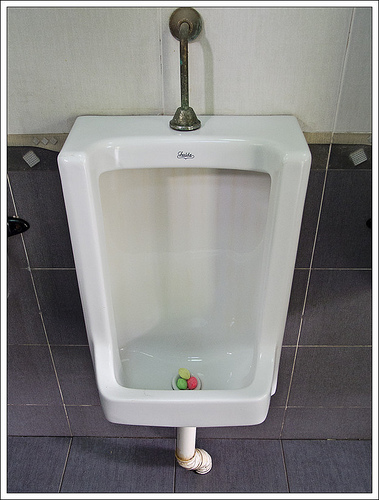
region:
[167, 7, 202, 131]
Rusty metal hardware coming out of the urinal.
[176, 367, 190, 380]
Yellow urinal cake.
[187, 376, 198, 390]
Pink urinal cake.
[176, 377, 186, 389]
A green urinal cake.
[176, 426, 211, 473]
A white pipe going into the floor.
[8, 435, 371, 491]
Four grey floor tile.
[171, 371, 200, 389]
White round drain under the urinal cakes.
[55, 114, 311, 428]
A long white urinal.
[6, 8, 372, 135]
White section of wall above a urinal.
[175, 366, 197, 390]
Pink, yellow and green urinal cakes.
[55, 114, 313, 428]
uninal in bathroom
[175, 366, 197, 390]
colored pieces in drain of urinal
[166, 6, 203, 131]
flush pipe for the urinal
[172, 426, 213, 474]
plumbing pipe for urinal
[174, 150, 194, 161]
name of urinal maker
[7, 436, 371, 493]
tiles on floor of bathroom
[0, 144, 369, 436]
gray tiles on wall of bathroom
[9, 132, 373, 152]
beige trim between tiles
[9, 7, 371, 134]
off white tiles in bathroom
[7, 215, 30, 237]
black object near urinal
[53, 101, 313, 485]
the toilet if porcelain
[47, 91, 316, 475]
toilet is color white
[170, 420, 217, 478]
a tube behind a toilet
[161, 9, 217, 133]
a pipe on top a toilet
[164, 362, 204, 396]
small balls on a toilet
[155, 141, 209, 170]
name of the company on toilet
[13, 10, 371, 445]
wall of bathroom is white and purple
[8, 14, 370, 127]
wall is color white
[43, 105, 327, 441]
toilet is for men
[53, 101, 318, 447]
toilet is mounted on the wall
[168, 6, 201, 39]
the circle is metal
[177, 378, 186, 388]
the shape is green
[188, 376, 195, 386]
the shape is red